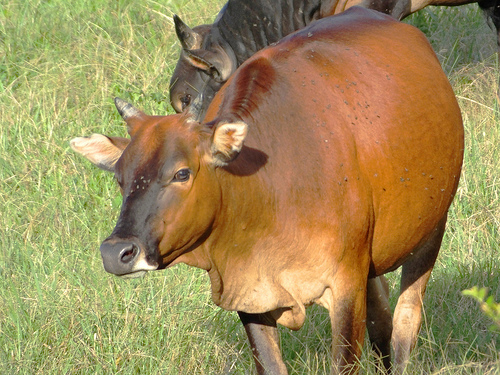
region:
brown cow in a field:
[62, 9, 465, 364]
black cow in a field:
[168, 0, 484, 121]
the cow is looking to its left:
[66, 79, 250, 279]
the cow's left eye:
[164, 164, 196, 190]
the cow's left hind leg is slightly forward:
[388, 210, 454, 369]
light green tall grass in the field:
[2, 260, 498, 372]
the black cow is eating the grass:
[171, 3, 498, 120]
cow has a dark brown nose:
[98, 147, 168, 282]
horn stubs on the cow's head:
[111, 86, 218, 139]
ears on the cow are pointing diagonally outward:
[66, 123, 247, 175]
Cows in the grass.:
[69, 0, 476, 374]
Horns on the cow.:
[107, 85, 209, 131]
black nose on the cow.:
[95, 229, 145, 276]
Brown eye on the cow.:
[163, 158, 195, 190]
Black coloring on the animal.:
[149, 3, 333, 111]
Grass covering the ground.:
[2, 3, 494, 373]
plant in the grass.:
[456, 273, 498, 332]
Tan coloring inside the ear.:
[210, 115, 247, 159]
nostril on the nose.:
[113, 242, 142, 266]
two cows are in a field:
[66, 4, 478, 371]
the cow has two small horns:
[103, 85, 209, 121]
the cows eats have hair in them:
[65, 115, 273, 174]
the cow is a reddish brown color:
[88, 13, 463, 347]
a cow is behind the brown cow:
[168, 4, 477, 106]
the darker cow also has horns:
[168, 10, 201, 52]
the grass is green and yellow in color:
[8, 14, 142, 372]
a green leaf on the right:
[461, 282, 499, 323]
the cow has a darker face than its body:
[111, 156, 166, 266]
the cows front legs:
[219, 302, 379, 371]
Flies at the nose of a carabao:
[126, 172, 158, 194]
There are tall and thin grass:
[287, 328, 442, 373]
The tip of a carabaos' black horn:
[194, 87, 211, 110]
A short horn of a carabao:
[166, 10, 203, 49]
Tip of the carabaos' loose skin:
[284, 317, 308, 337]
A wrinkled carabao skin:
[242, 0, 316, 43]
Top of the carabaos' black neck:
[207, 3, 255, 30]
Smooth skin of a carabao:
[400, 92, 457, 131]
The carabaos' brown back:
[232, 57, 284, 110]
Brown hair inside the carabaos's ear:
[221, 127, 241, 152]